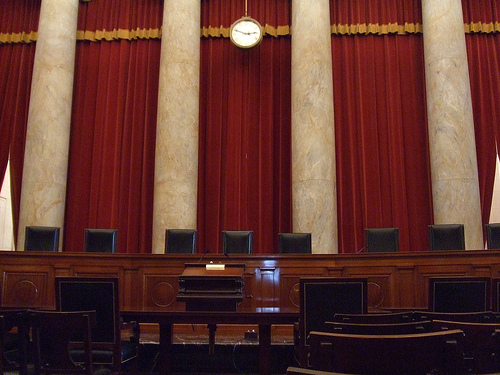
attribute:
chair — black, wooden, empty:
[55, 274, 121, 311]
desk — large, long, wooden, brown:
[120, 304, 289, 320]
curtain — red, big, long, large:
[207, 49, 285, 222]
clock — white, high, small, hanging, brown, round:
[227, 17, 263, 50]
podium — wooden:
[177, 258, 247, 311]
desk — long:
[0, 248, 488, 265]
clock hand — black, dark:
[232, 27, 246, 36]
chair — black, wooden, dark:
[300, 277, 369, 315]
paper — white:
[205, 263, 225, 272]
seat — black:
[164, 228, 199, 255]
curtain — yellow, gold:
[336, 23, 422, 34]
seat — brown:
[306, 330, 462, 360]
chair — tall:
[221, 229, 253, 254]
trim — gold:
[77, 28, 159, 42]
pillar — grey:
[152, 1, 200, 230]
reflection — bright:
[250, 261, 285, 311]